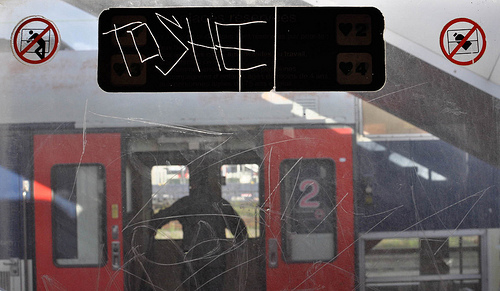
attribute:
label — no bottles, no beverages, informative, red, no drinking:
[442, 13, 484, 67]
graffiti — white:
[108, 8, 270, 78]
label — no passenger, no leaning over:
[10, 15, 60, 71]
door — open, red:
[263, 123, 361, 290]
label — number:
[337, 15, 369, 47]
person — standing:
[162, 156, 241, 280]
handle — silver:
[268, 236, 278, 268]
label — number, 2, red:
[292, 175, 322, 213]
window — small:
[281, 159, 338, 259]